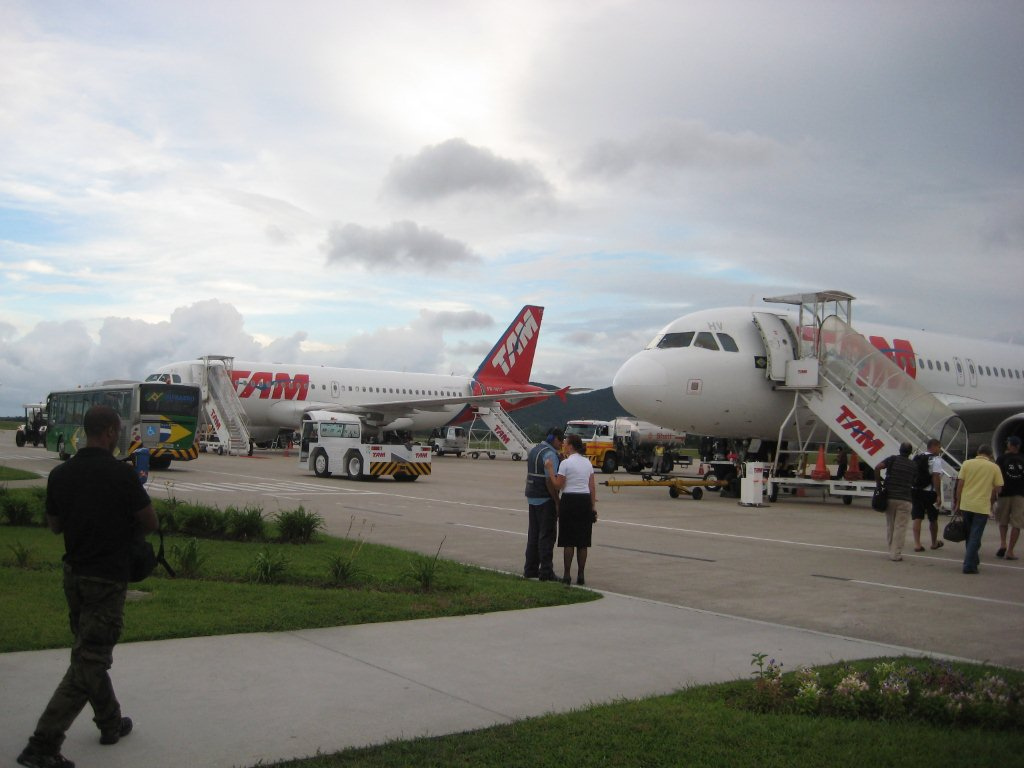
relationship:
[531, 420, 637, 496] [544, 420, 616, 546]
shirt on woman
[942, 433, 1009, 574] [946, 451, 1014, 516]
man wearing shirt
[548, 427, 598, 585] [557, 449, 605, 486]
woman wearing shirt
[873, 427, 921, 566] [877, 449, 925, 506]
man wearing shirt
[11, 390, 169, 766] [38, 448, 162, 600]
man wearing shirt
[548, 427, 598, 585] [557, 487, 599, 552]
woman wearing skirt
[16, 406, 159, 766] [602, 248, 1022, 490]
man walking to plane